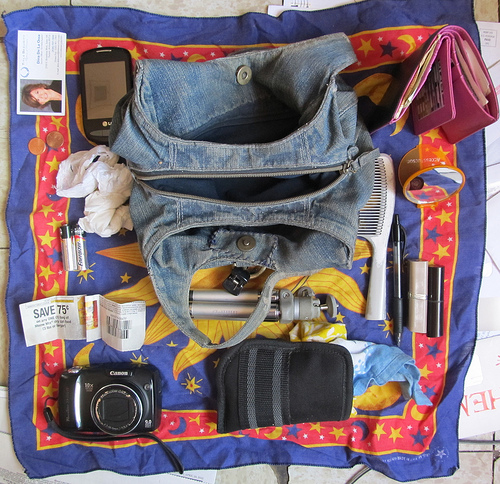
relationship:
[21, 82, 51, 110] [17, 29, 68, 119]
head on card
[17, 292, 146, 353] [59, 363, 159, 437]
coupon above camera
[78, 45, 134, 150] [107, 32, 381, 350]
phone underneath purse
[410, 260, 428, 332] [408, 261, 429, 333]
lipsitck beside lipsitck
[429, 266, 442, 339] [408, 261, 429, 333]
lipstick beside lipsitck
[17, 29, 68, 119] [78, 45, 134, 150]
card beside phone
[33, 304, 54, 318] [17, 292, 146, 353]
word on coupon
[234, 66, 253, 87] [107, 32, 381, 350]
button on purse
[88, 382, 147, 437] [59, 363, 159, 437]
lens on camera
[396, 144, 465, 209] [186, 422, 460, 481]
mirror on bandana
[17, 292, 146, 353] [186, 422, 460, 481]
coupon on bandana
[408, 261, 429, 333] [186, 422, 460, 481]
lipsitck on bandana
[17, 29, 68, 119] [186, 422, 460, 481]
card on bandana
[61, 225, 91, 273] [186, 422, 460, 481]
batteries on bandana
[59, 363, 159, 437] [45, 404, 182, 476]
camera has a strap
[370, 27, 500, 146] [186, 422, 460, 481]
wallet on bandana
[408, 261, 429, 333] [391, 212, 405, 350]
lipsitck beside pen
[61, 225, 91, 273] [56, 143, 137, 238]
batteries beneath tissue